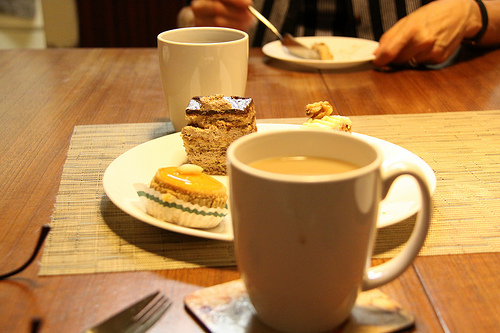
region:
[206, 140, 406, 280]
The cup has liquid in it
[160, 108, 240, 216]
there are sweets on the plate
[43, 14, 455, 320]
eating at a table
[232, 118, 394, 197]
coffee in the mug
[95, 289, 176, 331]
Fork next to the mug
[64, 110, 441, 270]
the plate is white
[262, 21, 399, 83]
eating from a plate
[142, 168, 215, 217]
the wrapper has a green stripe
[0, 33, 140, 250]
the table is wooden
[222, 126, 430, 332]
The closest coffee mug.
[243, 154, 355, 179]
Brown liquid inside a coffee cup.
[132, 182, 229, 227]
A green and white cupcake wrapper.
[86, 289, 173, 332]
The end of a four pronged fork on the table.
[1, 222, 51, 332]
The black ends of a pair of glasses.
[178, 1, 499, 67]
A person eating across the table.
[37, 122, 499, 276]
A tan mat in the center of the table.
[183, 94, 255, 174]
A tall thick dessert on a plate.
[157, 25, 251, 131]
White mug with no visible handle.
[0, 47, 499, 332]
A brown table.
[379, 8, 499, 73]
hand of a person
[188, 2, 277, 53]
hand of a person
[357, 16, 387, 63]
thumb of a person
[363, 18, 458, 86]
fingers of a person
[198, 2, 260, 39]
finger of a person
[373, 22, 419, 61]
index finger of a person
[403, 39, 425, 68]
middle finger of a person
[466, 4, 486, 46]
wrist of a person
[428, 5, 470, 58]
veins of a person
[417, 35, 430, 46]
knuckle of a person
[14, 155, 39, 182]
Small part of the wooden table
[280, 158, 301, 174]
Small patch of brown coffee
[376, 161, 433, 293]
White handle of coffee cup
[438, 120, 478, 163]
Tan placemat on the table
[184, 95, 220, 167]
One slice of cake on the white plate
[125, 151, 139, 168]
Small part of the white plate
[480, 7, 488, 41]
Black watch of the person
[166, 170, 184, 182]
Orange frosting on the cupcake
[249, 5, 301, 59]
Silverware that the person is using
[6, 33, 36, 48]
White floor in the distance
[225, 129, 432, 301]
a big white cup of coffee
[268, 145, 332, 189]
a lot of light brown coffee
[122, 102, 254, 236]
a plate of desserts and cake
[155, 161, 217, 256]
a piece of light brown dessert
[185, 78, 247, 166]
a piece of chocolate cake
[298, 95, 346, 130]
a big nut on a cake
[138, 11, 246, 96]
a white empty cup of coffee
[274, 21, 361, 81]
a piece of cake being eaten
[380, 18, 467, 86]
a persons big hand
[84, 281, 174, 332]
a big silver fork for eating